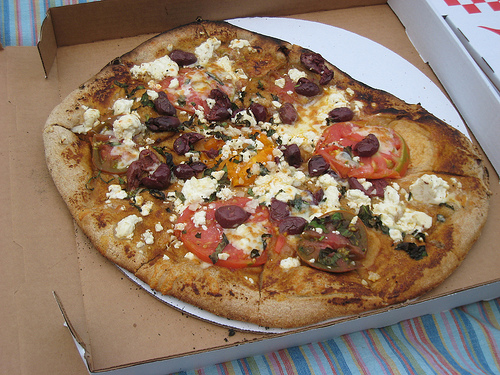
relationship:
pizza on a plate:
[45, 21, 490, 330] [57, 17, 475, 334]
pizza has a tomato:
[45, 21, 490, 330] [314, 123, 408, 182]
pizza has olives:
[45, 21, 490, 330] [138, 49, 379, 237]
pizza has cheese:
[45, 21, 490, 330] [69, 35, 449, 264]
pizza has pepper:
[45, 21, 490, 330] [168, 69, 230, 112]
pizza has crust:
[45, 21, 490, 330] [42, 19, 490, 328]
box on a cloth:
[0, 4, 498, 374] [1, 1, 500, 373]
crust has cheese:
[42, 19, 490, 328] [69, 35, 449, 264]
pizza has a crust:
[45, 21, 490, 330] [42, 19, 490, 328]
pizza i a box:
[45, 21, 490, 330] [0, 4, 498, 374]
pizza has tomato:
[45, 21, 490, 330] [314, 123, 408, 182]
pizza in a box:
[45, 21, 490, 330] [0, 4, 498, 374]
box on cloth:
[0, 4, 498, 374] [1, 1, 500, 373]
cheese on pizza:
[69, 35, 449, 264] [45, 21, 490, 330]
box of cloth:
[0, 4, 498, 374] [1, 1, 500, 373]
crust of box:
[42, 19, 490, 328] [0, 4, 498, 374]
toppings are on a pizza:
[96, 48, 459, 278] [45, 21, 490, 330]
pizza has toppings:
[45, 21, 490, 330] [96, 48, 459, 278]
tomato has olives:
[314, 123, 408, 182] [138, 49, 379, 237]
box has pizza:
[0, 4, 498, 374] [45, 21, 490, 330]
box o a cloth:
[0, 4, 498, 374] [1, 1, 500, 373]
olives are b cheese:
[138, 49, 379, 237] [69, 35, 449, 264]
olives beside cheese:
[138, 49, 379, 237] [69, 35, 449, 264]